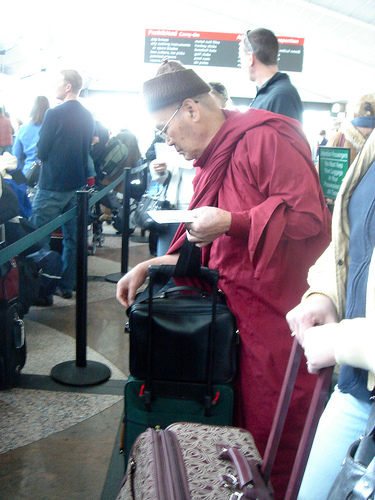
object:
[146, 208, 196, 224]
paper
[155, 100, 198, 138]
glasses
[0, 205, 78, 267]
belt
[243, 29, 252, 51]
sunglasses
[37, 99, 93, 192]
shirt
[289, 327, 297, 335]
ring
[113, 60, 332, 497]
man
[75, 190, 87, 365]
pole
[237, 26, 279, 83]
head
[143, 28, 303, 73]
red/black sign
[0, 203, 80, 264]
line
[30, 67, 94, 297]
person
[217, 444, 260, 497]
handle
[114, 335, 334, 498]
suitcase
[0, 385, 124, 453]
tile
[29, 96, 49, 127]
hair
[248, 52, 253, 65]
ear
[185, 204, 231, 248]
hand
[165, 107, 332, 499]
robe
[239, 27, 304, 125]
man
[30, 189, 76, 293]
jean pants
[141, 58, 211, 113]
cap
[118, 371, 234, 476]
suitcase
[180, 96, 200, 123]
ear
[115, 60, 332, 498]
he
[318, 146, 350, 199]
sign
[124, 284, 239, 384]
travel bag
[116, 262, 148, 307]
hand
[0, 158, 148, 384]
railing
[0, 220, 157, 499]
ground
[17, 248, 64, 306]
backpack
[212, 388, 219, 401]
red accent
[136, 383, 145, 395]
red accent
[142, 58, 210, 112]
hat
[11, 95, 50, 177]
person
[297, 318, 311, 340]
finger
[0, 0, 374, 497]
airport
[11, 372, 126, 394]
stripe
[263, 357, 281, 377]
red